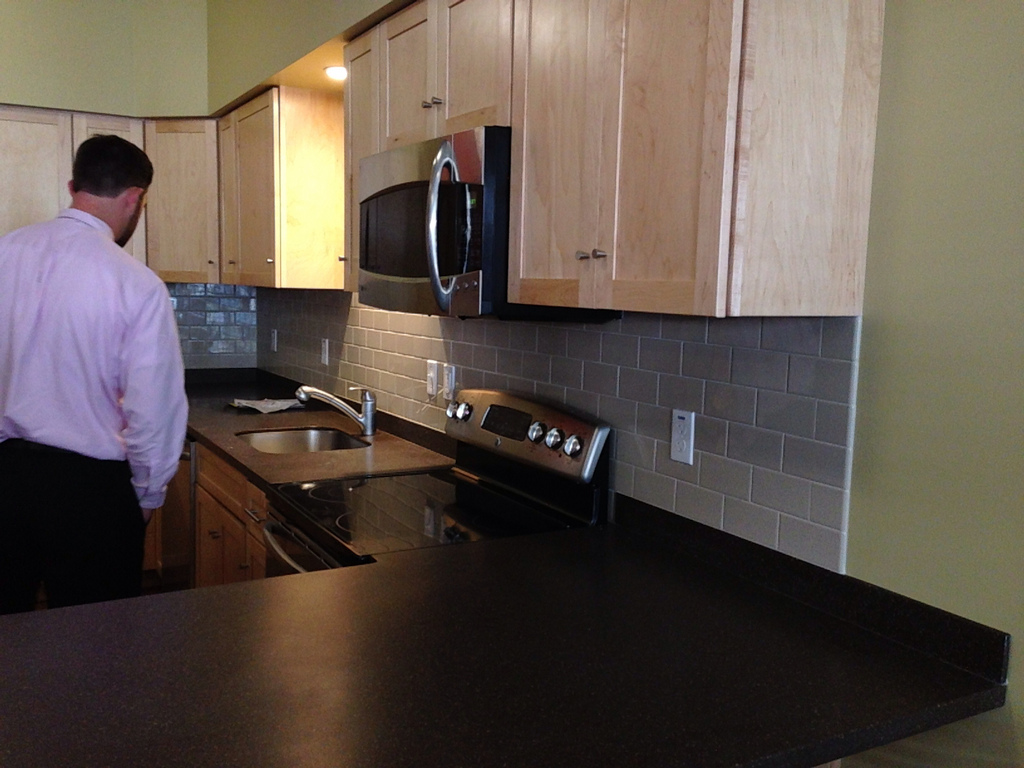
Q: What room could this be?
A: It is a kitchen.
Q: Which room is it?
A: It is a kitchen.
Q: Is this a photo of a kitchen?
A: Yes, it is showing a kitchen.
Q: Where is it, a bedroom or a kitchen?
A: It is a kitchen.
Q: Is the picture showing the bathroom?
A: No, the picture is showing the kitchen.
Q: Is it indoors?
A: Yes, it is indoors.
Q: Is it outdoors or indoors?
A: It is indoors.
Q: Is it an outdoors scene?
A: No, it is indoors.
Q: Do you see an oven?
A: Yes, there is an oven.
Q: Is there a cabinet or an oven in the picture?
A: Yes, there is an oven.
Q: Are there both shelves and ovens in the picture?
A: No, there is an oven but no shelves.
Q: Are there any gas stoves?
A: No, there are no gas stoves.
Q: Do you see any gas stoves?
A: No, there are no gas stoves.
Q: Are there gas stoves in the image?
A: No, there are no gas stoves.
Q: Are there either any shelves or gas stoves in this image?
A: No, there are no gas stoves or shelves.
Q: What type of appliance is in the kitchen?
A: The appliance is an oven.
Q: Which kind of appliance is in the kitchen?
A: The appliance is an oven.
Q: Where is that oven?
A: The oven is in the kitchen.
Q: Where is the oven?
A: The oven is in the kitchen.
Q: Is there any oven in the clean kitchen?
A: Yes, there is an oven in the kitchen.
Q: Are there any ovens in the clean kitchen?
A: Yes, there is an oven in the kitchen.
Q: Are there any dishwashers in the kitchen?
A: No, there is an oven in the kitchen.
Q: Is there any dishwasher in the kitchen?
A: No, there is an oven in the kitchen.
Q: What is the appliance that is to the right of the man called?
A: The appliance is an oven.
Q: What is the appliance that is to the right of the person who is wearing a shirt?
A: The appliance is an oven.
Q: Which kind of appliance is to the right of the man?
A: The appliance is an oven.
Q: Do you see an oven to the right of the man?
A: Yes, there is an oven to the right of the man.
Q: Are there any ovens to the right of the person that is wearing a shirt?
A: Yes, there is an oven to the right of the man.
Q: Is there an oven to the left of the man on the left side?
A: No, the oven is to the right of the man.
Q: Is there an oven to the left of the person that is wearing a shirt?
A: No, the oven is to the right of the man.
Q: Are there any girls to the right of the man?
A: No, there is an oven to the right of the man.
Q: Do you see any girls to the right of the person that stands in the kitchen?
A: No, there is an oven to the right of the man.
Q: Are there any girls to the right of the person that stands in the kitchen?
A: No, there is an oven to the right of the man.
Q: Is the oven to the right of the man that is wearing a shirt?
A: Yes, the oven is to the right of the man.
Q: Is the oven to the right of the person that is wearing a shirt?
A: Yes, the oven is to the right of the man.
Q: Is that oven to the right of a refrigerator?
A: No, the oven is to the right of the man.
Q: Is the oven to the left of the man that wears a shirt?
A: No, the oven is to the right of the man.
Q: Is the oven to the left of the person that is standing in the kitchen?
A: No, the oven is to the right of the man.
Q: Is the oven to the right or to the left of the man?
A: The oven is to the right of the man.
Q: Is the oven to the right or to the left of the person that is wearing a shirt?
A: The oven is to the right of the man.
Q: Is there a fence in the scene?
A: No, there are no fences.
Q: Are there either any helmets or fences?
A: No, there are no fences or helmets.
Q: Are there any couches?
A: No, there are no couches.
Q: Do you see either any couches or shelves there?
A: No, there are no couches or shelves.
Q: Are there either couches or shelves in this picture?
A: No, there are no couches or shelves.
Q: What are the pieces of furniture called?
A: The pieces of furniture are cabinets.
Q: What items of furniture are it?
A: The pieces of furniture are cabinets.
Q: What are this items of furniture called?
A: These are cabinets.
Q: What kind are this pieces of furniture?
A: These are cabinets.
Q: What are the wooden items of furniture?
A: The pieces of furniture are cabinets.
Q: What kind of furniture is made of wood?
A: The furniture is cabinets.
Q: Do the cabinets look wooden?
A: Yes, the cabinets are wooden.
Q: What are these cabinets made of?
A: The cabinets are made of wood.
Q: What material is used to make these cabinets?
A: The cabinets are made of wood.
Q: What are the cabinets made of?
A: The cabinets are made of wood.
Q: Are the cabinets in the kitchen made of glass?
A: No, the cabinets are made of wood.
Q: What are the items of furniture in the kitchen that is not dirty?
A: The pieces of furniture are cabinets.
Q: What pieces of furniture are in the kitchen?
A: The pieces of furniture are cabinets.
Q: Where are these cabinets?
A: The cabinets are in the kitchen.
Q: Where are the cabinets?
A: The cabinets are in the kitchen.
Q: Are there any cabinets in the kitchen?
A: Yes, there are cabinets in the kitchen.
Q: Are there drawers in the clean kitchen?
A: No, there are cabinets in the kitchen.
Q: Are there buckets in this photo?
A: No, there are no buckets.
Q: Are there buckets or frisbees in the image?
A: No, there are no buckets or frisbees.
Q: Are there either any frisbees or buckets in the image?
A: No, there are no buckets or frisbees.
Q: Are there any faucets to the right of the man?
A: Yes, there is a faucet to the right of the man.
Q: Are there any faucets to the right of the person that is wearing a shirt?
A: Yes, there is a faucet to the right of the man.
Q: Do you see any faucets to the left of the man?
A: No, the faucet is to the right of the man.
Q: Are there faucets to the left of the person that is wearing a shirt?
A: No, the faucet is to the right of the man.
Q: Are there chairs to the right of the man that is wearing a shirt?
A: No, there is a faucet to the right of the man.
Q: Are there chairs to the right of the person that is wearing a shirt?
A: No, there is a faucet to the right of the man.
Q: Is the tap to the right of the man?
A: Yes, the tap is to the right of the man.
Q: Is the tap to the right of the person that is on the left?
A: Yes, the tap is to the right of the man.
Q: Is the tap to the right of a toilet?
A: No, the tap is to the right of the man.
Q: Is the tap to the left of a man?
A: No, the tap is to the right of a man.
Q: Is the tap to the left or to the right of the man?
A: The tap is to the right of the man.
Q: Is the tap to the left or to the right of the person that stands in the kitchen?
A: The tap is to the right of the man.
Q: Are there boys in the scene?
A: No, there are no boys.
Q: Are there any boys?
A: No, there are no boys.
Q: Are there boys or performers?
A: No, there are no boys or performers.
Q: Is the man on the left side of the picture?
A: Yes, the man is on the left of the image.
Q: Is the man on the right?
A: No, the man is on the left of the image.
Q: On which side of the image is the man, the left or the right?
A: The man is on the left of the image.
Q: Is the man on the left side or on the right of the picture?
A: The man is on the left of the image.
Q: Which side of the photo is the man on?
A: The man is on the left of the image.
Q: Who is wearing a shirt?
A: The man is wearing a shirt.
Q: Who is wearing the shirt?
A: The man is wearing a shirt.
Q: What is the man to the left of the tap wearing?
A: The man is wearing a shirt.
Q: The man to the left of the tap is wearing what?
A: The man is wearing a shirt.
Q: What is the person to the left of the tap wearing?
A: The man is wearing a shirt.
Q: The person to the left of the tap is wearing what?
A: The man is wearing a shirt.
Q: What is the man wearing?
A: The man is wearing a shirt.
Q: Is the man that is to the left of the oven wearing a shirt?
A: Yes, the man is wearing a shirt.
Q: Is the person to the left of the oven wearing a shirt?
A: Yes, the man is wearing a shirt.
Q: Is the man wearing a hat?
A: No, the man is wearing a shirt.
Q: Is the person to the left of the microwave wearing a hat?
A: No, the man is wearing a shirt.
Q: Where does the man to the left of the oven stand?
A: The man stands in the kitchen.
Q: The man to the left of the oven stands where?
A: The man stands in the kitchen.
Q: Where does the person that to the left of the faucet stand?
A: The man stands in the kitchen.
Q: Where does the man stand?
A: The man stands in the kitchen.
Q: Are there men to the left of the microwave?
A: Yes, there is a man to the left of the microwave.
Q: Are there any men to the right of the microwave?
A: No, the man is to the left of the microwave.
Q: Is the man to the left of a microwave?
A: Yes, the man is to the left of a microwave.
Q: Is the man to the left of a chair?
A: No, the man is to the left of a microwave.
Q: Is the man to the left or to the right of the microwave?
A: The man is to the left of the microwave.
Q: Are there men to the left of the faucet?
A: Yes, there is a man to the left of the faucet.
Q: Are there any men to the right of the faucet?
A: No, the man is to the left of the faucet.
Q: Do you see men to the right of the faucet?
A: No, the man is to the left of the faucet.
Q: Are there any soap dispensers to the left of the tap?
A: No, there is a man to the left of the tap.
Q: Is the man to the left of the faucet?
A: Yes, the man is to the left of the faucet.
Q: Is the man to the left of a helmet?
A: No, the man is to the left of the faucet.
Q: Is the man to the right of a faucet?
A: No, the man is to the left of a faucet.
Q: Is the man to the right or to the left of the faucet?
A: The man is to the left of the faucet.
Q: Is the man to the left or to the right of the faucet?
A: The man is to the left of the faucet.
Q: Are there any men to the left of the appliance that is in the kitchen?
A: Yes, there is a man to the left of the oven.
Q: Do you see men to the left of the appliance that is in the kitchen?
A: Yes, there is a man to the left of the oven.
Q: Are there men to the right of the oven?
A: No, the man is to the left of the oven.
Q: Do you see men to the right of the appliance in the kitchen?
A: No, the man is to the left of the oven.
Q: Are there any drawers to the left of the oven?
A: No, there is a man to the left of the oven.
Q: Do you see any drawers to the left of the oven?
A: No, there is a man to the left of the oven.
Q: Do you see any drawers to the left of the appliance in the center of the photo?
A: No, there is a man to the left of the oven.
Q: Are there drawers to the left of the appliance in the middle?
A: No, there is a man to the left of the oven.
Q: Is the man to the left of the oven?
A: Yes, the man is to the left of the oven.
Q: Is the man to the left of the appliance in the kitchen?
A: Yes, the man is to the left of the oven.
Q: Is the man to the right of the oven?
A: No, the man is to the left of the oven.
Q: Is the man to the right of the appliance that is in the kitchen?
A: No, the man is to the left of the oven.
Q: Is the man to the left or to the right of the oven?
A: The man is to the left of the oven.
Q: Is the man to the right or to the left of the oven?
A: The man is to the left of the oven.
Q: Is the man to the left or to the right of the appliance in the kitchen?
A: The man is to the left of the oven.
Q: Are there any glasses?
A: No, there are no glasses.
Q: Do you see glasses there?
A: No, there are no glasses.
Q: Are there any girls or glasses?
A: No, there are no glasses or girls.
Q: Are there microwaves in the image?
A: Yes, there is a microwave.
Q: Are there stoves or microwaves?
A: Yes, there is a microwave.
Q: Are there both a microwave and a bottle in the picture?
A: No, there is a microwave but no bottles.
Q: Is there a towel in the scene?
A: No, there are no towels.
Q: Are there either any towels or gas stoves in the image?
A: No, there are no towels or gas stoves.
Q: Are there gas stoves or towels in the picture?
A: No, there are no towels or gas stoves.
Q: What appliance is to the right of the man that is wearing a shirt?
A: The appliance is a microwave.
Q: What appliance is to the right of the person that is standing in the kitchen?
A: The appliance is a microwave.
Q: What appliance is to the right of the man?
A: The appliance is a microwave.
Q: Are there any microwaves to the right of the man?
A: Yes, there is a microwave to the right of the man.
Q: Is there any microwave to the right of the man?
A: Yes, there is a microwave to the right of the man.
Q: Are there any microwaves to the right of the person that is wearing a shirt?
A: Yes, there is a microwave to the right of the man.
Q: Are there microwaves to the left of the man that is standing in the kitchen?
A: No, the microwave is to the right of the man.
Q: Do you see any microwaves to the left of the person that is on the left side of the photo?
A: No, the microwave is to the right of the man.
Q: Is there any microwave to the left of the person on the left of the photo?
A: No, the microwave is to the right of the man.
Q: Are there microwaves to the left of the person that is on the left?
A: No, the microwave is to the right of the man.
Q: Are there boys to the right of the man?
A: No, there is a microwave to the right of the man.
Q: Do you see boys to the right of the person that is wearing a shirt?
A: No, there is a microwave to the right of the man.